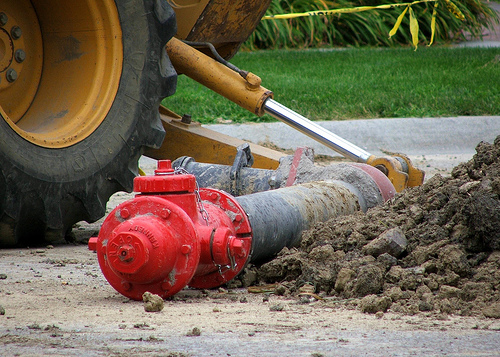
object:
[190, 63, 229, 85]
paint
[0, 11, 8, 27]
bolts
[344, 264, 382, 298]
rocks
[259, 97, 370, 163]
pole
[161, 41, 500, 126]
lawn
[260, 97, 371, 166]
steel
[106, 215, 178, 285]
cap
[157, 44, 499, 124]
grass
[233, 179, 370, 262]
pole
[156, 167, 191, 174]
chain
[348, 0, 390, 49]
foliage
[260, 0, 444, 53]
caution tape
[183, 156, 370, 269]
pipe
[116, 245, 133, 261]
bolts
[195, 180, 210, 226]
chain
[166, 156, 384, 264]
pipe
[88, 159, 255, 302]
hydrant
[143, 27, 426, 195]
crane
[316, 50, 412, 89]
luscious grass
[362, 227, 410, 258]
rocks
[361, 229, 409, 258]
clump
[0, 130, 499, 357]
dirt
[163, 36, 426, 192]
brace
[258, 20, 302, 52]
fern leaves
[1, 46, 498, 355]
ground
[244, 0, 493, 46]
plants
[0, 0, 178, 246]
tire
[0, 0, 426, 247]
truck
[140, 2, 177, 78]
grooves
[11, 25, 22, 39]
bolt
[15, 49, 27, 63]
bolt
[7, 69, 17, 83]
bolt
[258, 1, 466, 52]
tape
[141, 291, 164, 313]
clump